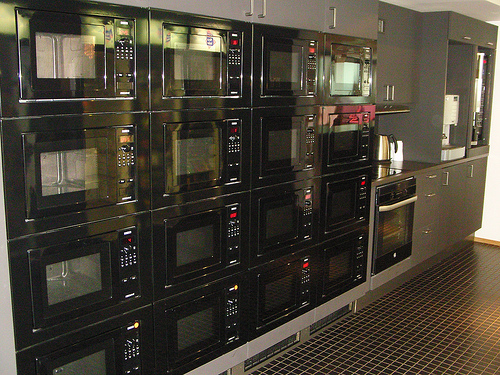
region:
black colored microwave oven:
[16, 8, 136, 100]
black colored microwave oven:
[163, 23, 242, 98]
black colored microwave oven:
[328, 42, 371, 97]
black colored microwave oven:
[23, 131, 133, 216]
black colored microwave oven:
[259, 109, 315, 175]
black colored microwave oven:
[328, 115, 374, 165]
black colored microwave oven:
[31, 225, 143, 332]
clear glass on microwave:
[34, 33, 96, 78]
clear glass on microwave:
[173, 43, 214, 79]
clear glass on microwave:
[268, 50, 300, 82]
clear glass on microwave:
[42, 148, 99, 193]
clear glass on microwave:
[268, 128, 300, 163]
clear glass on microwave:
[329, 122, 359, 156]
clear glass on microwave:
[44, 255, 102, 307]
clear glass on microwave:
[176, 226, 216, 262]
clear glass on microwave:
[264, 202, 292, 237]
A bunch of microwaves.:
[2, 2, 377, 372]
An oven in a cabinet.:
[369, 173, 419, 279]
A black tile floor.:
[245, 238, 499, 371]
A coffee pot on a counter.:
[372, 131, 392, 164]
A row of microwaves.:
[1, 1, 379, 120]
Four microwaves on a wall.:
[243, 166, 372, 343]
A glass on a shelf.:
[383, 80, 395, 111]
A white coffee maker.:
[438, 93, 466, 161]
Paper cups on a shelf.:
[391, 139, 403, 166]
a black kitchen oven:
[372, 171, 418, 282]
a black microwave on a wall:
[321, 31, 378, 103]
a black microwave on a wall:
[322, 106, 375, 173]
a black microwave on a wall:
[322, 172, 372, 234]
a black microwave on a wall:
[323, 222, 373, 302]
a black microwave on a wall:
[250, 19, 320, 106]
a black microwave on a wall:
[250, 104, 318, 186]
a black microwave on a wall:
[249, 177, 320, 259]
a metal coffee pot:
[368, 129, 400, 166]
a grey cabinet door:
[376, 1, 419, 109]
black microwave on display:
[32, 15, 129, 100]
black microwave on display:
[19, 122, 131, 213]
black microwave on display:
[160, 203, 247, 267]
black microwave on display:
[143, 24, 233, 104]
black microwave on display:
[246, 43, 311, 103]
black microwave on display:
[258, 116, 315, 173]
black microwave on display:
[264, 188, 322, 248]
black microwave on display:
[247, 267, 307, 320]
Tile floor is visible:
[401, 295, 498, 366]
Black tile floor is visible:
[375, 324, 410, 352]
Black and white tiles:
[417, 297, 489, 363]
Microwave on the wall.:
[16, 6, 137, 101]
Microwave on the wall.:
[21, 129, 121, 221]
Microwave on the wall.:
[160, 20, 241, 96]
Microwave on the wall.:
[160, 118, 240, 194]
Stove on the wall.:
[370, 175, 417, 275]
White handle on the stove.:
[375, 193, 416, 208]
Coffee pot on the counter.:
[373, 130, 396, 165]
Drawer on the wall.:
[415, 167, 441, 188]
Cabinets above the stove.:
[377, 0, 415, 107]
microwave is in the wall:
[320, 34, 380, 103]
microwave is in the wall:
[318, 105, 380, 175]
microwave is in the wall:
[323, 169, 374, 234]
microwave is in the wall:
[325, 226, 370, 303]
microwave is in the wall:
[250, 23, 320, 105]